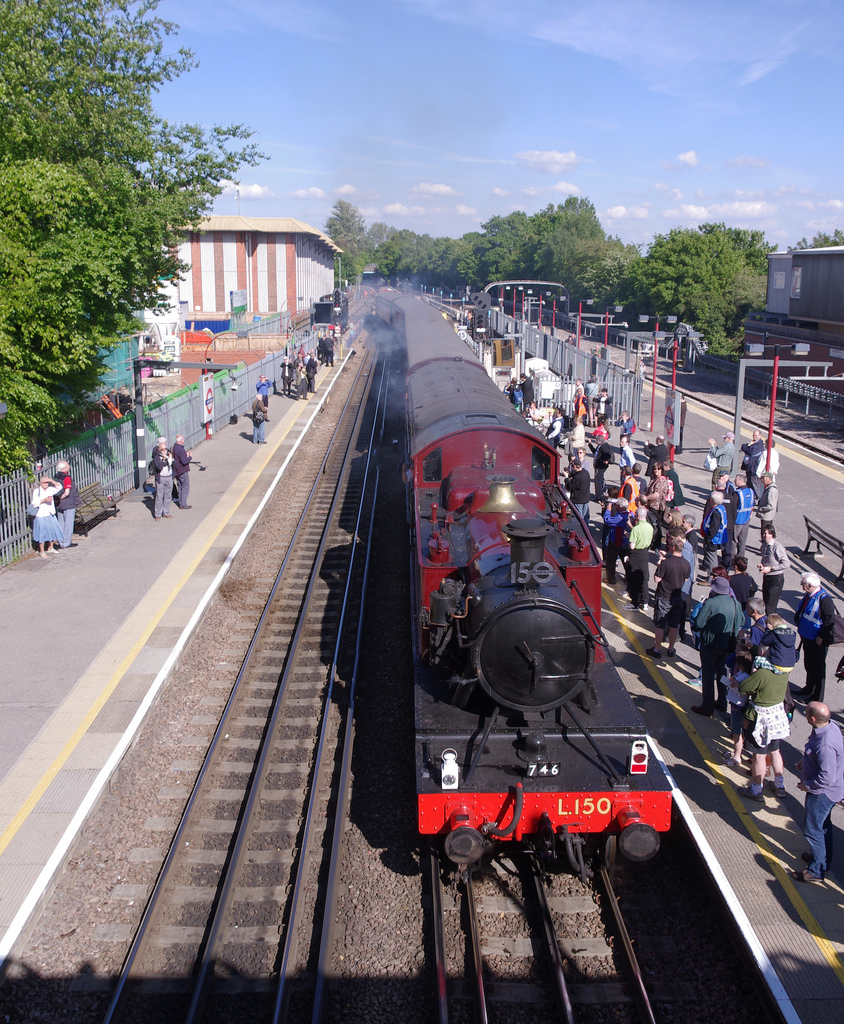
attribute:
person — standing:
[648, 462, 672, 518]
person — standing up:
[653, 534, 692, 661]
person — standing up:
[678, 512, 704, 564]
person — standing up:
[730, 476, 756, 572]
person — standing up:
[757, 436, 780, 495]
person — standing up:
[751, 526, 787, 615]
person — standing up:
[793, 572, 837, 700]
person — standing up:
[796, 703, 837, 882]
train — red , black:
[315, 237, 776, 898]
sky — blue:
[172, 4, 748, 271]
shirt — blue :
[790, 705, 817, 772]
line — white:
[6, 346, 357, 965]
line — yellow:
[6, 349, 329, 849]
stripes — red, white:
[164, 234, 297, 323]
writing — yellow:
[542, 787, 615, 817]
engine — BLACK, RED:
[401, 412, 669, 861]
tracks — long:
[109, 294, 647, 1016]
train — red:
[372, 282, 674, 878]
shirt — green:
[742, 664, 788, 708]